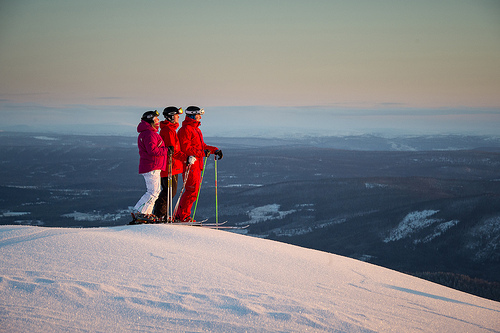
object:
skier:
[133, 109, 174, 221]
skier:
[176, 105, 224, 223]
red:
[159, 119, 189, 177]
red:
[175, 116, 218, 222]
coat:
[136, 122, 168, 174]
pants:
[132, 169, 163, 215]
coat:
[160, 120, 187, 178]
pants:
[154, 173, 179, 219]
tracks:
[13, 277, 352, 330]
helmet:
[141, 110, 161, 125]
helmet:
[162, 106, 183, 124]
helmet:
[184, 105, 204, 120]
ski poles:
[169, 146, 173, 224]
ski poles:
[173, 160, 193, 222]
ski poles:
[214, 152, 218, 230]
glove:
[189, 155, 197, 164]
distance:
[221, 138, 499, 286]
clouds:
[0, 102, 495, 134]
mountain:
[1, 224, 498, 329]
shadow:
[0, 225, 128, 247]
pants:
[177, 169, 201, 222]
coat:
[177, 116, 219, 170]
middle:
[152, 106, 198, 224]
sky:
[1, 1, 498, 113]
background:
[0, 1, 499, 288]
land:
[0, 130, 498, 295]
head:
[141, 110, 160, 127]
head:
[162, 106, 183, 124]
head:
[185, 105, 205, 121]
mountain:
[1, 102, 497, 142]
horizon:
[0, 105, 497, 141]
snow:
[383, 209, 449, 244]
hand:
[167, 146, 174, 155]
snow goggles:
[143, 109, 160, 118]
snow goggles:
[163, 107, 183, 116]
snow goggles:
[186, 108, 205, 114]